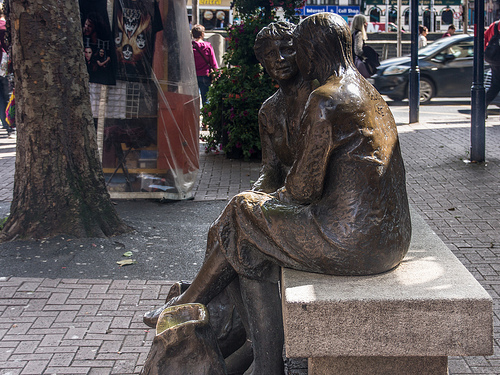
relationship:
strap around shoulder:
[193, 46, 217, 63] [200, 39, 216, 60]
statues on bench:
[258, 63, 352, 188] [384, 292, 428, 318]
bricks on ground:
[46, 305, 110, 334] [154, 237, 174, 263]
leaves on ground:
[120, 234, 138, 274] [154, 237, 174, 263]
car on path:
[369, 40, 462, 100] [410, 113, 478, 174]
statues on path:
[258, 63, 352, 188] [410, 113, 478, 174]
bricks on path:
[46, 305, 110, 334] [410, 113, 478, 174]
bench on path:
[384, 292, 428, 318] [410, 113, 478, 174]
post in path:
[476, 46, 487, 56] [410, 113, 478, 174]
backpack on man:
[483, 45, 498, 59] [269, 1, 405, 289]